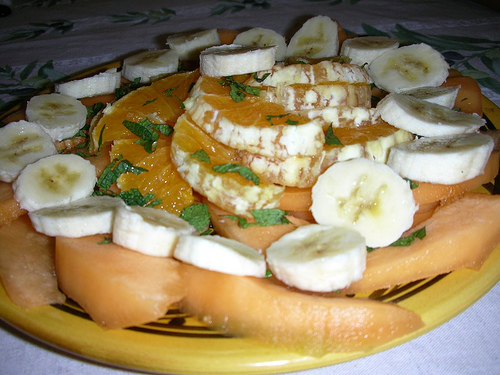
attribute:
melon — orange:
[148, 229, 360, 354]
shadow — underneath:
[2, 310, 152, 373]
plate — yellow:
[55, 325, 250, 370]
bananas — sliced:
[288, 93, 470, 280]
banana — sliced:
[308, 155, 419, 252]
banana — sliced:
[386, 130, 498, 186]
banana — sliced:
[377, 91, 485, 138]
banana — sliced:
[369, 40, 449, 96]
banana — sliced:
[265, 221, 370, 292]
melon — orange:
[183, 262, 419, 348]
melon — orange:
[356, 198, 498, 280]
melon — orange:
[61, 229, 191, 321]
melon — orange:
[1, 206, 56, 302]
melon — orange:
[455, 72, 485, 113]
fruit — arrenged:
[57, 236, 181, 331]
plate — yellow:
[2, 45, 499, 373]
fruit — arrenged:
[187, 77, 320, 154]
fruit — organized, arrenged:
[267, 223, 367, 291]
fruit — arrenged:
[111, 205, 194, 255]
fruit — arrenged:
[254, 60, 376, 87]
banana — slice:
[200, 42, 275, 78]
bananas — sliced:
[38, 66, 415, 295]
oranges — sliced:
[157, 103, 327, 198]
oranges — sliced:
[216, 42, 396, 126]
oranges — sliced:
[87, 73, 219, 194]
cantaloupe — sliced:
[432, 211, 487, 256]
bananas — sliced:
[2, 77, 192, 257]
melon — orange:
[68, 238, 411, 348]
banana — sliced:
[272, 227, 379, 299]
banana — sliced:
[319, 164, 420, 248]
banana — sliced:
[391, 134, 494, 180]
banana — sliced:
[383, 96, 490, 138]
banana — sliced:
[183, 220, 269, 273]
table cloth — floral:
[0, 3, 498, 88]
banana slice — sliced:
[29, 195, 126, 237]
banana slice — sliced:
[10, 151, 98, 210]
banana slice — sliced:
[0, 117, 59, 182]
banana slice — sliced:
[24, 91, 89, 141]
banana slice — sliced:
[57, 67, 123, 98]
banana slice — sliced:
[120, 45, 180, 85]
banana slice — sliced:
[167, 26, 222, 63]